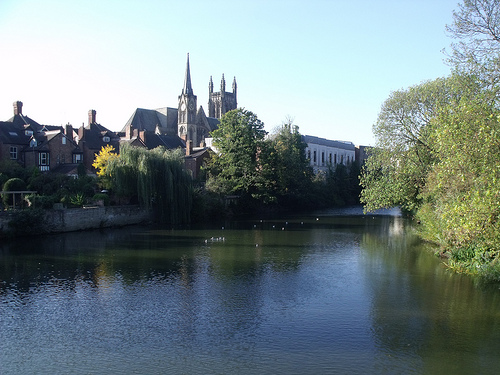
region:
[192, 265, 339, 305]
lake of green water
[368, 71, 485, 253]
group of green trees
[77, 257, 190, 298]
reflection on green water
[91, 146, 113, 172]
yellow tree in group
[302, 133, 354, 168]
white building on side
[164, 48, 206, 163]
church with grey steeple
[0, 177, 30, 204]
green manicured round bush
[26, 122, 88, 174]
large brick building by lake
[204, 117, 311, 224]
large tall green tree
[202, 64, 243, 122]
square tower with spires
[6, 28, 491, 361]
A riverside town scene is pictured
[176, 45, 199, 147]
This building has a clock tower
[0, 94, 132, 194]
A house is near the river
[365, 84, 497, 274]
Trees are growing on the river bank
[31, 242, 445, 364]
This is a river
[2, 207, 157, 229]
A wall is built along the river bank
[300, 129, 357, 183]
This building is white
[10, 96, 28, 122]
A chimney is on the roof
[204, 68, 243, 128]
This building has a tall tower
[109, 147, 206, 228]
A willow tree is hanging over the river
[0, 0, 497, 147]
clear sky with little clouds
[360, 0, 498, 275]
tree to the right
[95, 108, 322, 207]
group of trees in front of buildings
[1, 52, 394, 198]
group of homes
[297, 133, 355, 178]
white house with gray roof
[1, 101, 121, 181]
brown house to the far left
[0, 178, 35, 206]
small bridge to the left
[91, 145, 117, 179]
bright yellow tree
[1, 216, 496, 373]
calm body of water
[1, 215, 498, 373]
clear body of water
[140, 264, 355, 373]
The water is visible.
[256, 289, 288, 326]
The water is visible.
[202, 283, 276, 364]
The water is visible.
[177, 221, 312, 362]
The water is visible.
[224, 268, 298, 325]
The water is visible.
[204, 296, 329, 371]
The water is visible.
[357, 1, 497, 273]
three trees on the side of the river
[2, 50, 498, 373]
river between trees and buildings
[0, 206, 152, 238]
brick retaining wall on the side of the river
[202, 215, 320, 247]
small white birds on the water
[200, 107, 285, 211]
tall green tree on the side of the river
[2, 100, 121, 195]
brown brick home overlooking the lake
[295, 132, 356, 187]
the back of a white building over the river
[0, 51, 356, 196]
buildings with view of the lake and trees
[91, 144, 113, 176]
yellow leaves on a tree branch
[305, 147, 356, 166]
eight windows on the white building